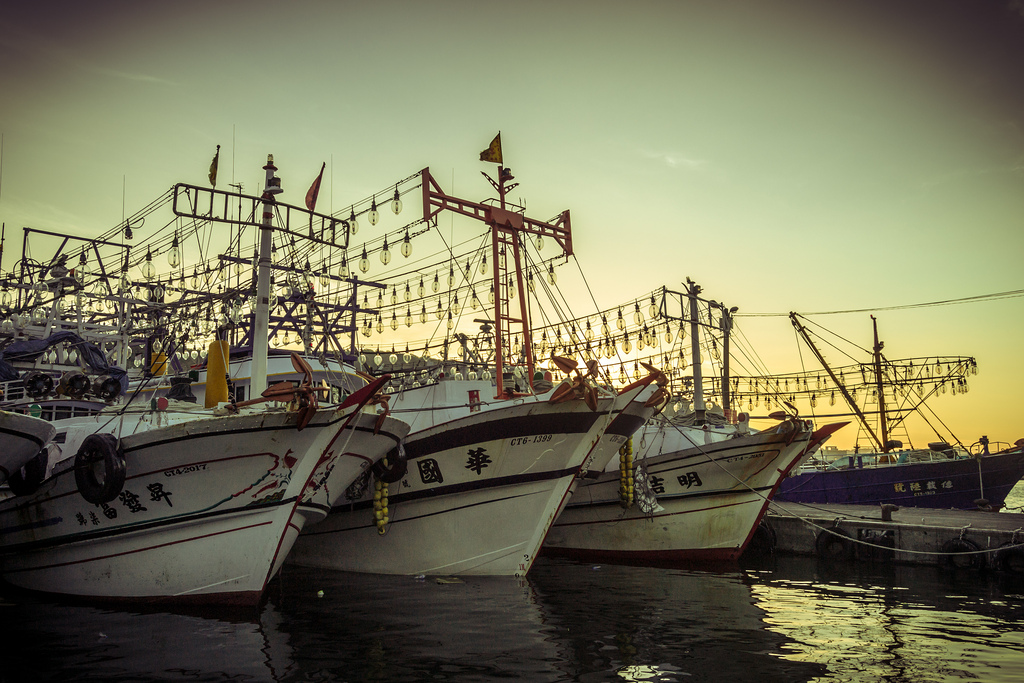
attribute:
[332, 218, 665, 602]
boat — parked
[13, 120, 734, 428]
wires — hanging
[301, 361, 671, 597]
boat — parked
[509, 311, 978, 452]
sunset — behind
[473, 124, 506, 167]
flag — flapping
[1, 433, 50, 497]
tire — hanging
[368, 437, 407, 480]
tire — hanging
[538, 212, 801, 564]
boat — blue